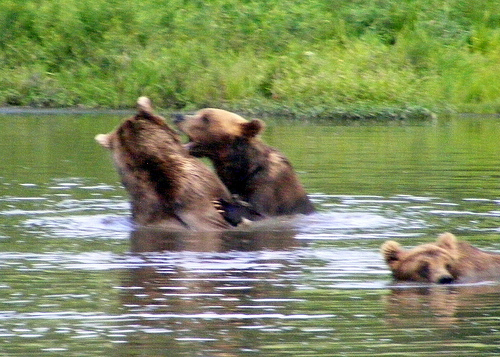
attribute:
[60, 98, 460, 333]
water —  green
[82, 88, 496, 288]
few animals —  a few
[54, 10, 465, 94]
trees —  green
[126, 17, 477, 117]
bushes —  green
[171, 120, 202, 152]
mouth —  bear's,  open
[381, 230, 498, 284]
bear — grizzly, baby, brown, submerged, wild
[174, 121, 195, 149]
mouth —  bear's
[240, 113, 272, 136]
ear —  bear's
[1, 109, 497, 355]
water — calm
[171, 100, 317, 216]
bear — brown, stadig, wild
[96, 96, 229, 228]
bear — black, brown, leaning, leaig, stadig, wild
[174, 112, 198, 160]
bear's mouth — open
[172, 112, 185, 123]
nose — black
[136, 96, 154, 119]
ear — white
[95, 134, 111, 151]
ear — white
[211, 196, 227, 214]
claws — long, log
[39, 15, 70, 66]
bush — green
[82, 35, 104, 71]
bush — green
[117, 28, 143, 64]
bush — green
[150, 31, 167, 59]
bush — green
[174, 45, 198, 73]
bush — green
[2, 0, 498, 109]
vegetatio — gree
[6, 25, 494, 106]
vegetation —  green